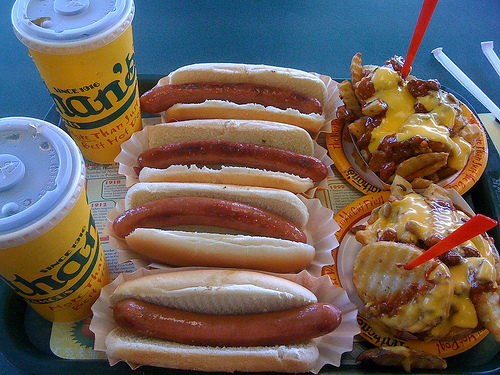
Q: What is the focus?
A: Lunch.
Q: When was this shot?
A: Daytime.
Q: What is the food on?
A: Tray.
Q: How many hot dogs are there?
A: 4.